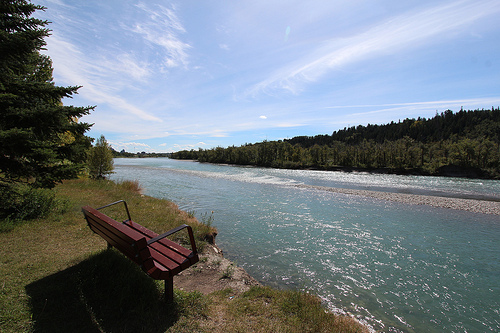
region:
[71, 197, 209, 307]
a red bench by some water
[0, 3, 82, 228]
a tall tree by some water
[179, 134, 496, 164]
a line of trees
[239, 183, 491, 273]
a river during the day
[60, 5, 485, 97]
slight amount of clouds in sky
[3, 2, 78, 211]
a pine tree on left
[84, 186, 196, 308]
a red wooden bench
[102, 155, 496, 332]
red bench beside the water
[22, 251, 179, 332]
shadow behind the red bench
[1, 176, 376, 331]
shadow on the ground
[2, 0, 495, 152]
sky is bright blue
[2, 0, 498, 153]
sky has white, puffy clouds in it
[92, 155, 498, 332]
the water has ripples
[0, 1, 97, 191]
tall green tree beside the water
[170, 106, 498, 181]
small hill by the water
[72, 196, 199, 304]
red bench on the ground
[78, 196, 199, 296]
empty, red bench beside the water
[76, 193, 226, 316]
a brown wooden bench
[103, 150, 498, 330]
a serene flowing river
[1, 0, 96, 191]
a large spruce tree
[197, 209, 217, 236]
a small shrub on a riverbank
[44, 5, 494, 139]
a peaceful cloudy sky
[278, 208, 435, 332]
small ripples in a river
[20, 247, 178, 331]
a shadow cast by a bench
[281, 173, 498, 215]
a sandbar in a river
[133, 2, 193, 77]
a cloud formation in the sky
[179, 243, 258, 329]
a small patch of dirt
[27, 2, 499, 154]
clouds in blue sky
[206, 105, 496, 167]
pine trees on hill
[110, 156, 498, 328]
surface of river water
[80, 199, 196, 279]
bench with metal arms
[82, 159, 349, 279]
red wood bench facing water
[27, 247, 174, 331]
shadow of bench on grass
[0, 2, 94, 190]
needles on pine tree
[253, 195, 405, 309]
light reflection on water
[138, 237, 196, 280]
curved edge of bench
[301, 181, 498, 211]
gravel in shallow river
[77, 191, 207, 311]
bench on the side of a river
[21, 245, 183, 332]
shadow of a bench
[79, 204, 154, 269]
back of a bench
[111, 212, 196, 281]
seat of a bench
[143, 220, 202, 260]
right hand rail on a bench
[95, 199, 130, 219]
left hand rail on a bench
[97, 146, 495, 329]
water in a river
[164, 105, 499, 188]
trees on the bank of a river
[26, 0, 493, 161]
bright blue sky with clouds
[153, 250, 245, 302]
dirt beneath a bench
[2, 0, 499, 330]
a sunny clear day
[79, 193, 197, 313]
an empty brown bench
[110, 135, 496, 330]
a clear blue lake